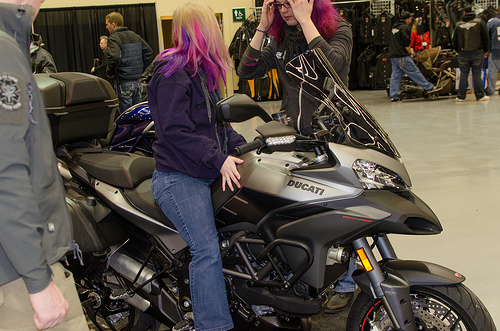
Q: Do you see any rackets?
A: No, there are no rackets.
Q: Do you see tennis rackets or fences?
A: No, there are no tennis rackets or fences.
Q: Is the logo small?
A: Yes, the logo is small.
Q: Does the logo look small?
A: Yes, the logo is small.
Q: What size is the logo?
A: The logo is small.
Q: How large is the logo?
A: The logo is small.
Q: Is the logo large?
A: No, the logo is small.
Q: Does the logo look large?
A: No, the logo is small.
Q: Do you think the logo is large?
A: No, the logo is small.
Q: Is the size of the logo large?
A: No, the logo is small.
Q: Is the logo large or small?
A: The logo is small.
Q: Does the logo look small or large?
A: The logo is small.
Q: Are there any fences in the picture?
A: No, there are no fences.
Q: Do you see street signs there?
A: Yes, there is a street sign.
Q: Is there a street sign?
A: Yes, there is a street sign.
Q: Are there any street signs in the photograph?
A: Yes, there is a street sign.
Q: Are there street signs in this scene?
A: Yes, there is a street sign.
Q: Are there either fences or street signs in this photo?
A: Yes, there is a street sign.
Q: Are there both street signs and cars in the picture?
A: No, there is a street sign but no cars.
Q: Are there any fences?
A: No, there are no fences.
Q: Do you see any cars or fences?
A: No, there are no fences or cars.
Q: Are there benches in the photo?
A: No, there are no benches.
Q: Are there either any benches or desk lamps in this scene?
A: No, there are no benches or desk lamps.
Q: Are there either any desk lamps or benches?
A: No, there are no benches or desk lamps.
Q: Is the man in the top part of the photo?
A: Yes, the man is in the top of the image.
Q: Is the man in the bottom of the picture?
A: No, the man is in the top of the image.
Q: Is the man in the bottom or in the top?
A: The man is in the top of the image.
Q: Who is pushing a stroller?
A: The man is pushing a stroller.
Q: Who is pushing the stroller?
A: The man is pushing a stroller.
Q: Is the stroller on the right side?
A: Yes, the stroller is on the right of the image.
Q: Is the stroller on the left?
A: No, the stroller is on the right of the image.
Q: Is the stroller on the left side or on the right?
A: The stroller is on the right of the image.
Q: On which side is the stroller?
A: The stroller is on the right of the image.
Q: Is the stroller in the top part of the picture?
A: Yes, the stroller is in the top of the image.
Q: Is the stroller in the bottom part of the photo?
A: No, the stroller is in the top of the image.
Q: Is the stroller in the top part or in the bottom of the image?
A: The stroller is in the top of the image.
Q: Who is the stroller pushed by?
A: The stroller is pushed by the man.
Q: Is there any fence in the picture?
A: No, there are no fences.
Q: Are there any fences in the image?
A: No, there are no fences.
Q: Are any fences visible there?
A: No, there are no fences.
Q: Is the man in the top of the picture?
A: Yes, the man is in the top of the image.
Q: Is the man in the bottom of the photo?
A: No, the man is in the top of the image.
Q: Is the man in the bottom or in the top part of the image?
A: The man is in the top of the image.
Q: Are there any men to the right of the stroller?
A: Yes, there is a man to the right of the stroller.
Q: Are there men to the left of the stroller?
A: No, the man is to the right of the stroller.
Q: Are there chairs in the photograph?
A: No, there are no chairs.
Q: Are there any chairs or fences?
A: No, there are no chairs or fences.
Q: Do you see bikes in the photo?
A: Yes, there is a bike.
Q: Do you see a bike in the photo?
A: Yes, there is a bike.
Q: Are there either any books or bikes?
A: Yes, there is a bike.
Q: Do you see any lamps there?
A: No, there are no lamps.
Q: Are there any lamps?
A: No, there are no lamps.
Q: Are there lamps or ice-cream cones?
A: No, there are no lamps or ice-cream cones.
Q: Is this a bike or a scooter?
A: This is a bike.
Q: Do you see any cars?
A: No, there are no cars.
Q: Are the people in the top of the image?
A: Yes, the people are in the top of the image.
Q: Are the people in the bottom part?
A: No, the people are in the top of the image.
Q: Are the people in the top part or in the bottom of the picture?
A: The people are in the top of the image.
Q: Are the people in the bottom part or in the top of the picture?
A: The people are in the top of the image.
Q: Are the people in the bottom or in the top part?
A: The people are in the top of the image.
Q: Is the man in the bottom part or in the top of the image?
A: The man is in the top of the image.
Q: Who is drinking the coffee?
A: The man is drinking the coffee.